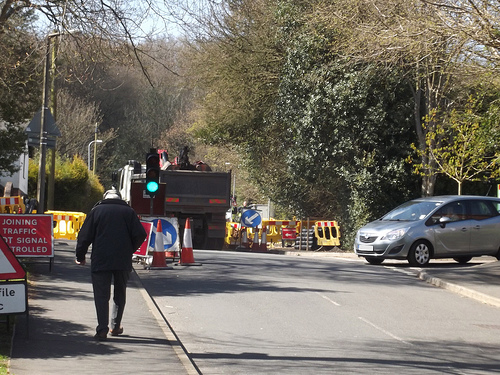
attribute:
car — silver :
[354, 193, 498, 267]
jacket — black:
[73, 198, 148, 273]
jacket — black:
[72, 193, 150, 281]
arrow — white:
[243, 210, 258, 225]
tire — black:
[415, 239, 430, 263]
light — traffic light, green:
[142, 149, 164, 197]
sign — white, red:
[3, 205, 60, 263]